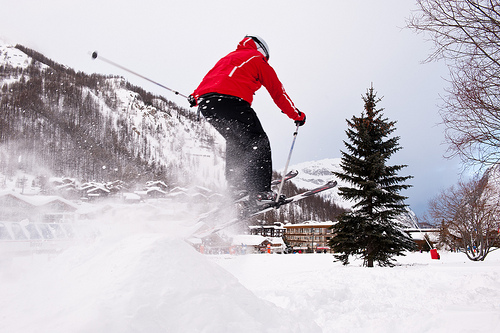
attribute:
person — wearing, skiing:
[187, 40, 304, 190]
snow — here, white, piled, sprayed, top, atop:
[76, 188, 197, 290]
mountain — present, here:
[31, 52, 122, 145]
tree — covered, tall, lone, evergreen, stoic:
[338, 109, 398, 233]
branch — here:
[326, 171, 379, 196]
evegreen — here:
[348, 88, 443, 232]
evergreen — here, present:
[356, 105, 412, 219]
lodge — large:
[278, 221, 371, 279]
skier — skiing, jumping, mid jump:
[162, 17, 310, 187]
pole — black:
[77, 37, 174, 109]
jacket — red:
[197, 47, 297, 106]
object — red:
[428, 246, 469, 285]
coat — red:
[204, 47, 303, 102]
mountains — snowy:
[55, 72, 113, 114]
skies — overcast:
[284, 21, 405, 118]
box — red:
[425, 247, 456, 270]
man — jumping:
[160, 40, 307, 192]